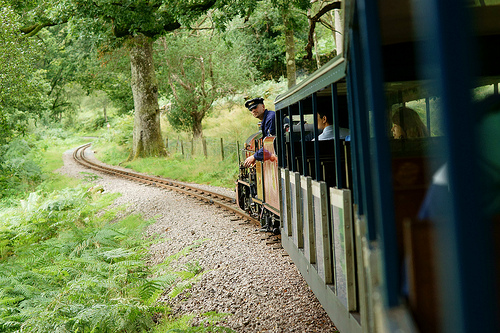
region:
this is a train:
[208, 0, 488, 331]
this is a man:
[236, 57, 283, 173]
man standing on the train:
[233, 79, 295, 216]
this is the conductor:
[240, 84, 283, 148]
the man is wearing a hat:
[237, 81, 268, 124]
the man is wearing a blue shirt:
[250, 107, 279, 140]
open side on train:
[263, 84, 406, 226]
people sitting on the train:
[299, 94, 436, 164]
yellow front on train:
[236, 127, 291, 227]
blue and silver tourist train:
[220, 78, 481, 305]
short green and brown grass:
[178, 158, 212, 173]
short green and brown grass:
[61, 265, 96, 300]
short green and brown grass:
[40, 305, 65, 327]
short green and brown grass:
[11, 230, 52, 263]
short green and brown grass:
[66, 295, 111, 325]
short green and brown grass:
[19, 217, 64, 252]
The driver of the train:
[242, 96, 273, 128]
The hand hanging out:
[245, 158, 252, 165]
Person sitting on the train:
[316, 112, 333, 139]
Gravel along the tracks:
[246, 266, 291, 303]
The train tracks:
[189, 189, 210, 196]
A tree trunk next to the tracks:
[134, 85, 157, 150]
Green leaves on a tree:
[110, 7, 155, 27]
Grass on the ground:
[222, 115, 244, 133]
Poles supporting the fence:
[203, 140, 225, 157]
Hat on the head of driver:
[244, 100, 259, 107]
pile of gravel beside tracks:
[222, 249, 274, 309]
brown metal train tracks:
[139, 172, 216, 210]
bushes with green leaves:
[31, 228, 126, 309]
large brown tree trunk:
[124, 33, 167, 163]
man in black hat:
[240, 95, 268, 122]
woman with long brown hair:
[377, 104, 433, 146]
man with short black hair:
[295, 101, 350, 147]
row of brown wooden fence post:
[155, 132, 244, 163]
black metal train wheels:
[237, 182, 278, 231]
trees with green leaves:
[102, 0, 208, 46]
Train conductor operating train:
[244, 94, 279, 166]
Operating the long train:
[234, 52, 496, 324]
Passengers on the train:
[288, 110, 440, 144]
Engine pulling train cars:
[234, 21, 481, 331]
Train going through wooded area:
[170, 0, 310, 237]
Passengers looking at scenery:
[293, 103, 417, 148]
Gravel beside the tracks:
[121, 173, 236, 270]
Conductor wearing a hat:
[236, 94, 283, 166]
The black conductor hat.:
[243, 95, 265, 110]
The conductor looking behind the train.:
[240, 93, 274, 176]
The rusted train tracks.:
[72, 140, 220, 249]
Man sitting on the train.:
[313, 104, 344, 144]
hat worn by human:
[245, 94, 263, 110]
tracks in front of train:
[72, 137, 252, 222]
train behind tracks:
[230, 2, 499, 332]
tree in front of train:
[159, 46, 234, 147]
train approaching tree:
[232, 2, 499, 330]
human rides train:
[310, 105, 347, 141]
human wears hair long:
[384, 108, 428, 143]